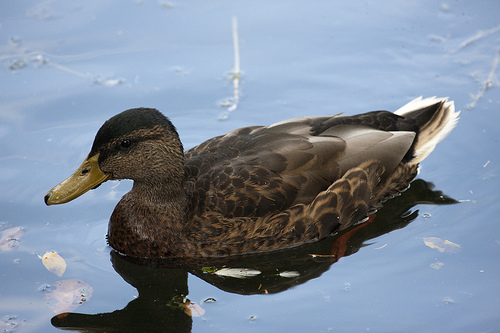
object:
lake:
[22, 3, 499, 93]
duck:
[41, 92, 460, 262]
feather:
[230, 145, 343, 203]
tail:
[396, 91, 460, 161]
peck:
[32, 170, 91, 207]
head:
[39, 103, 193, 211]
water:
[0, 0, 498, 332]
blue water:
[0, 0, 499, 332]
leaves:
[31, 250, 78, 283]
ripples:
[352, 244, 430, 311]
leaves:
[33, 269, 98, 318]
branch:
[221, 12, 246, 120]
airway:
[70, 165, 92, 177]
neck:
[131, 170, 191, 190]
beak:
[42, 163, 107, 206]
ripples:
[0, 3, 473, 108]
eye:
[119, 132, 135, 154]